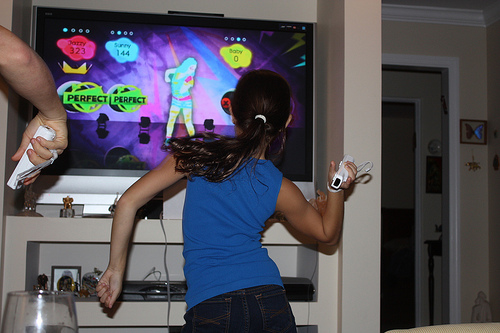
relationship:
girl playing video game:
[94, 70, 356, 333] [34, 10, 323, 186]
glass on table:
[1, 290, 83, 332] [7, 315, 101, 331]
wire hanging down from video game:
[159, 215, 170, 330] [30, 1, 333, 175]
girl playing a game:
[94, 70, 356, 333] [33, 10, 310, 177]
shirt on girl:
[181, 156, 285, 311] [94, 70, 356, 333]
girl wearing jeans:
[94, 70, 356, 333] [191, 274, 299, 329]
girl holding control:
[94, 70, 356, 333] [330, 154, 374, 191]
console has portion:
[277, 268, 330, 314] [170, 195, 182, 223]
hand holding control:
[327, 157, 357, 193] [329, 152, 371, 191]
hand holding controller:
[8, 112, 65, 182] [7, 125, 56, 190]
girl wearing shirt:
[94, 70, 356, 333] [180, 154, 280, 287]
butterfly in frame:
[468, 122, 483, 137] [452, 111, 494, 156]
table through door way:
[424, 238, 449, 325] [382, 51, 462, 323]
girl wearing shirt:
[169, 70, 295, 330] [185, 156, 284, 299]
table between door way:
[424, 201, 448, 325] [382, 53, 461, 330]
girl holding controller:
[94, 70, 356, 333] [334, 160, 352, 190]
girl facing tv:
[94, 70, 356, 333] [39, 20, 333, 184]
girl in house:
[94, 70, 356, 333] [1, 0, 487, 331]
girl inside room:
[94, 70, 356, 333] [3, 4, 498, 330]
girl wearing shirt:
[94, 70, 356, 333] [181, 150, 281, 306]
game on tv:
[35, 6, 314, 182] [31, 5, 319, 184]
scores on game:
[48, 23, 251, 93] [34, 21, 243, 151]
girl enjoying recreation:
[94, 70, 356, 333] [55, 28, 362, 330]